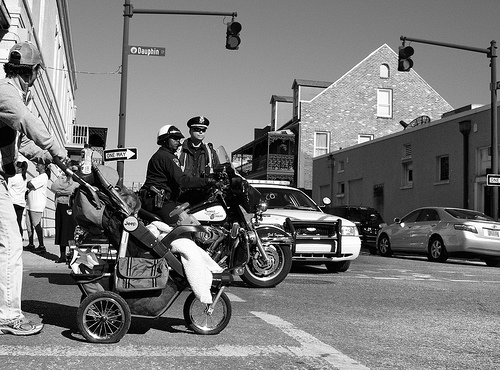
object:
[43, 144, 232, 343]
stroller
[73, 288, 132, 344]
back wheel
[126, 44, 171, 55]
street sign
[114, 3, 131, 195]
pole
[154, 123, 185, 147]
helmet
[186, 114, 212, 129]
hat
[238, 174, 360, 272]
car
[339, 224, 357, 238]
headlight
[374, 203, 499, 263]
car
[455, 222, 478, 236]
tail light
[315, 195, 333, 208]
mirror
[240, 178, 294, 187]
light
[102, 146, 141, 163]
sign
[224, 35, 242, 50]
lights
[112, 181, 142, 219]
child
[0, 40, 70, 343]
person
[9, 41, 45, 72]
baseball cap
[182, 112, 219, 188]
cop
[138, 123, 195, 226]
cop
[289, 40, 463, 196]
building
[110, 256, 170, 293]
bag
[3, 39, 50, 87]
head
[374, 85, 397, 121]
window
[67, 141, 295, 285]
motorcycle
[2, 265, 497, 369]
street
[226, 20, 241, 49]
traffic lights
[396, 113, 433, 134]
satellite dish